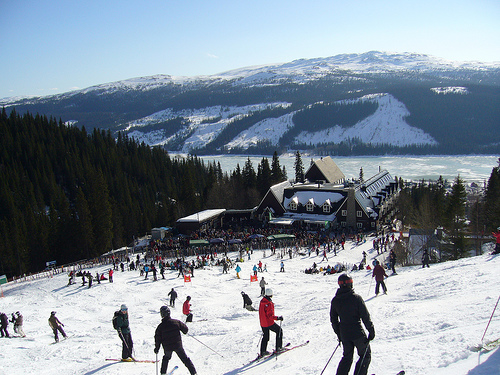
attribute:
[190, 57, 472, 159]
mountain — snow-covered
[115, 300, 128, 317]
hat — ski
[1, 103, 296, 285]
pines — tall 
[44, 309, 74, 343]
skier — standing 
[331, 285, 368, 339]
jacket — black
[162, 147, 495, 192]
lake — frozen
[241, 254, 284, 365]
skier — standing 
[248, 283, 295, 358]
ski outfit — red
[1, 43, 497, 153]
mountain — far, top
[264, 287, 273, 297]
hat — white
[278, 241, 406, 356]
skier — standing 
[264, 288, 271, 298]
knit cap — white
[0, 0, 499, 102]
sky — blue 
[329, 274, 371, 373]
skier — standing 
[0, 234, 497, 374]
snow — white 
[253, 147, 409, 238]
building — distance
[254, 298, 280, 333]
jacket — red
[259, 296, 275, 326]
coat — red 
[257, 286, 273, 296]
hat — white 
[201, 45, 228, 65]
clouds — white 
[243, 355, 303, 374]
snow — white 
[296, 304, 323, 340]
snow — white 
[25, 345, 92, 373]
snow — white 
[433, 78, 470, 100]
clearing — smaller